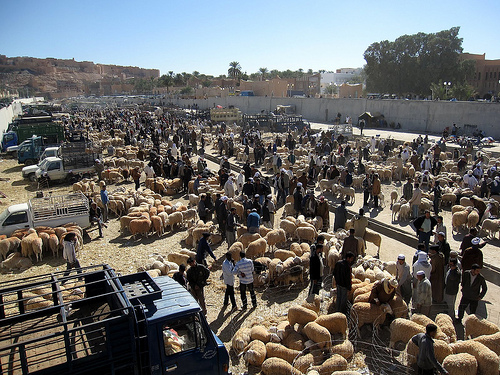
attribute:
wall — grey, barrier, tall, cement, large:
[246, 92, 495, 135]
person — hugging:
[222, 248, 242, 307]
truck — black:
[1, 272, 227, 374]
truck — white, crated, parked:
[1, 180, 85, 236]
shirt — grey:
[411, 280, 433, 308]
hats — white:
[397, 253, 430, 282]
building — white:
[321, 66, 367, 98]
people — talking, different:
[198, 192, 225, 227]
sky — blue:
[11, 4, 213, 56]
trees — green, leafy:
[364, 28, 465, 94]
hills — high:
[74, 45, 161, 95]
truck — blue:
[0, 128, 24, 159]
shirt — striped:
[236, 259, 259, 286]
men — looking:
[394, 246, 452, 309]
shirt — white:
[225, 181, 238, 200]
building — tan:
[241, 76, 299, 97]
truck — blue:
[18, 145, 45, 165]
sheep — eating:
[288, 304, 349, 350]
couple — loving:
[211, 248, 264, 313]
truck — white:
[20, 164, 48, 182]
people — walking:
[293, 119, 469, 223]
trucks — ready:
[19, 107, 94, 186]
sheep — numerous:
[243, 208, 318, 283]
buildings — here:
[160, 52, 384, 101]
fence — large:
[106, 96, 280, 117]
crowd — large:
[148, 106, 380, 219]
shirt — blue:
[244, 212, 263, 236]